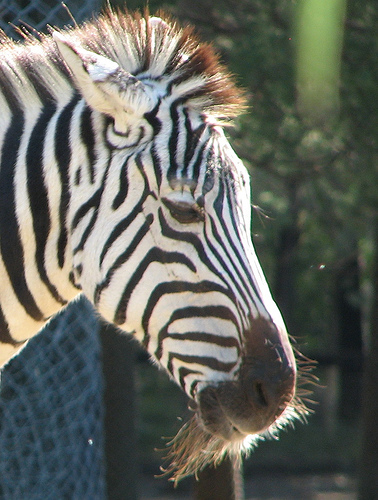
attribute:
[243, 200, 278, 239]
eyelashes — long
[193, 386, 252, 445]
mouth — black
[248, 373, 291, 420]
nose — black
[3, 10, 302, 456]
animal — black and white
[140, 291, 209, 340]
stripes — black and white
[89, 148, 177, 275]
stripe — black and white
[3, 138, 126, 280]
fur — black and gray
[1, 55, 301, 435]
fur — black and white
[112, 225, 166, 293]
stripes — black and white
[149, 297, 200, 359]
stripe — black and white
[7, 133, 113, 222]
stripes — black, white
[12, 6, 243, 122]
mane — sticking up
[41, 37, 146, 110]
ears — back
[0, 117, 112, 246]
stripes — black, white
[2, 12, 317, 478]
stripes —  black and white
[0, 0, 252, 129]
mane — black and white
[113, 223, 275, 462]
stripes — thin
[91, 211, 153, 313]
stripe — black and white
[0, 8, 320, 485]
fur — stripped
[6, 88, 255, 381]
stripes — white, black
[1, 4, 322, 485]
animal — black and white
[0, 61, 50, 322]
stripe — wide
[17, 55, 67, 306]
stripe — wide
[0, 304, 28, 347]
stripe — wide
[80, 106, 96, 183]
stripe — wide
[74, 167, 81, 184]
stripe — wide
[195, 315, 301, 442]
muzzle — black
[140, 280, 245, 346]
stripe — black and white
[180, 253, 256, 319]
stripes — black and white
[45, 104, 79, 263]
stripe — black, white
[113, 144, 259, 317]
stripes — vertical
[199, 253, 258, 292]
stripes — black, white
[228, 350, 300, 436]
nose — brown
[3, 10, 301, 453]
fur — Black and white 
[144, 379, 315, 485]
hair — fine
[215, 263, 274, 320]
stripes — black and white